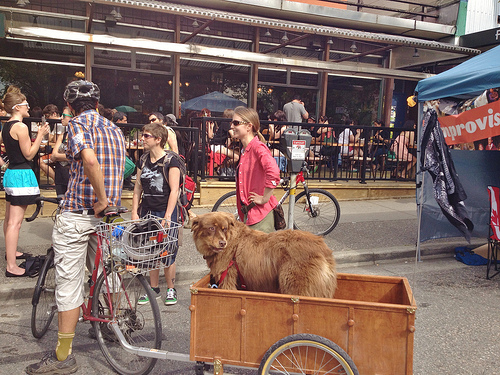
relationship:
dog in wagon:
[189, 211, 336, 298] [195, 269, 417, 373]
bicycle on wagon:
[23, 194, 183, 374] [185, 260, 422, 374]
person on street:
[193, 96, 299, 238] [320, 185, 434, 259]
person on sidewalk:
[132, 123, 184, 305] [0, 192, 482, 287]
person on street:
[4, 97, 34, 137] [17, 225, 47, 245]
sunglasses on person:
[230, 118, 245, 127] [230, 106, 278, 234]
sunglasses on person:
[230, 120, 249, 126] [132, 123, 184, 305]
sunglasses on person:
[11, 102, 29, 107] [0, 82, 52, 275]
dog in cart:
[185, 207, 359, 294] [155, 259, 427, 373]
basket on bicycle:
[85, 221, 146, 269] [34, 171, 199, 312]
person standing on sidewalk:
[229, 105, 286, 234] [318, 194, 495, 262]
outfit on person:
[1, 118, 41, 204] [0, 84, 49, 279]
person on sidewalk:
[0, 84, 49, 279] [0, 192, 482, 287]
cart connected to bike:
[190, 258, 425, 371] [42, 205, 184, 352]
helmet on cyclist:
[62, 80, 102, 104] [24, 79, 124, 374]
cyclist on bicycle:
[24, 79, 124, 374] [22, 194, 180, 374]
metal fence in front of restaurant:
[0, 112, 413, 201] [2, 0, 497, 189]